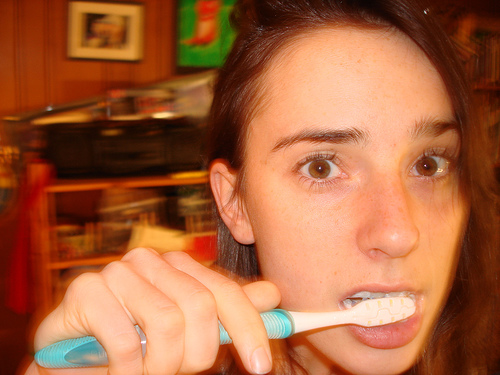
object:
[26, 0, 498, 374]
woman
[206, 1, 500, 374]
hair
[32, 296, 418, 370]
toothbrush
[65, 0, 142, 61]
frame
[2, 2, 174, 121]
wall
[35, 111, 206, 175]
radio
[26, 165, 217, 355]
cabinet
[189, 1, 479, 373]
head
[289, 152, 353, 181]
eye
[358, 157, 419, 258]
nose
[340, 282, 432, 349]
mouth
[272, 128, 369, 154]
eyebrow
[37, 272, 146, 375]
finger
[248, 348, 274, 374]
fingernail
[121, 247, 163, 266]
knuckle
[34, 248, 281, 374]
hand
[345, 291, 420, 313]
teeth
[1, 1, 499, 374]
photo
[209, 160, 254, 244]
right ear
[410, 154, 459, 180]
left eye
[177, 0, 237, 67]
painting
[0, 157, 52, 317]
dress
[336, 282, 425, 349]
lips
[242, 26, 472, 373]
face